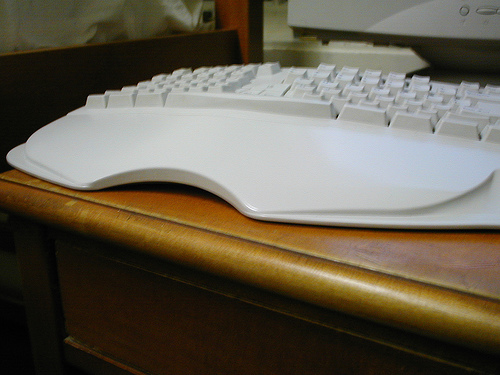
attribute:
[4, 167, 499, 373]
desk — stained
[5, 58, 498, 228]
keyboard — white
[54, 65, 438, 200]
keyboard — large , white 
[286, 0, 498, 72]
monitor — white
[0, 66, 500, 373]
desk — wood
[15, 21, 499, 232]
keyboard — white 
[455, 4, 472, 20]
button — small, circular